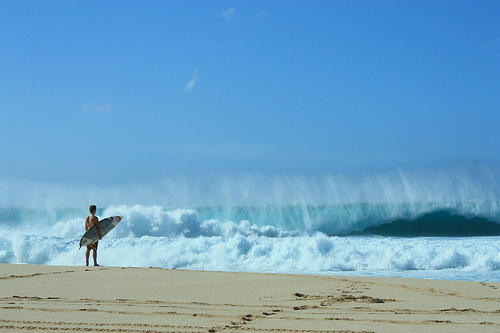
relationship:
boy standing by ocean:
[80, 206, 98, 268] [1, 187, 499, 284]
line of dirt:
[235, 268, 332, 281] [223, 261, 291, 281]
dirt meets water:
[223, 261, 291, 281] [226, 237, 334, 263]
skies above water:
[6, 0, 493, 125] [35, 174, 499, 275]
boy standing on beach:
[85, 205, 102, 266] [2, 258, 499, 330]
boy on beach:
[85, 205, 102, 266] [3, 217, 492, 331]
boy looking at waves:
[85, 205, 102, 266] [249, 167, 498, 215]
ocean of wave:
[0, 201, 500, 280] [0, 182, 499, 284]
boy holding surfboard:
[85, 205, 102, 266] [77, 214, 124, 249]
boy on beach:
[85, 205, 102, 266] [0, 171, 498, 330]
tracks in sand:
[9, 309, 399, 331] [78, 271, 383, 303]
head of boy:
[90, 203, 102, 216] [85, 205, 102, 266]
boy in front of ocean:
[85, 205, 102, 266] [5, 165, 495, 265]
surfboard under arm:
[77, 214, 124, 249] [94, 217, 104, 240]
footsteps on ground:
[201, 288, 382, 332] [0, 263, 500, 333]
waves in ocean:
[5, 188, 496, 276] [0, 161, 499, 284]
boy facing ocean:
[85, 205, 102, 266] [4, 176, 499, 268]